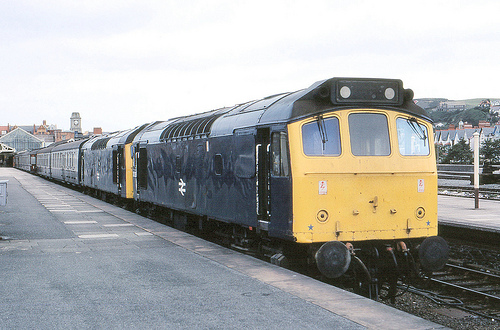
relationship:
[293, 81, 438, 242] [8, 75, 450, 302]
front of train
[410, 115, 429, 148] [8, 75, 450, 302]
windshield wiper of train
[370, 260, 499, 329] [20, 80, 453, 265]
train track next to train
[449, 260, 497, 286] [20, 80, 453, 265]
train track next to train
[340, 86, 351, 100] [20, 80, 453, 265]
headlight on front of train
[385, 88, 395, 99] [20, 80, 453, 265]
headlight on front of train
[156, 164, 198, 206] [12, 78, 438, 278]
logo on side of train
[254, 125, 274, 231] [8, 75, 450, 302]
area to get into train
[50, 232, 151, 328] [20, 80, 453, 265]
cement platform on left side of train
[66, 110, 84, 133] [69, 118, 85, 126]
tower with clock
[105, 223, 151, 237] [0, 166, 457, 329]
rectangle in cement platform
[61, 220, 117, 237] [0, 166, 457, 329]
rectangle in cement platform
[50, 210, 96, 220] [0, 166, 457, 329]
rectangle in cement platform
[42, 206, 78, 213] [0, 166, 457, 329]
rectangle in cement platform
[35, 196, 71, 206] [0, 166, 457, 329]
rectangle in cement platform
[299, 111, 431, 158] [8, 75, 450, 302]
windows of a train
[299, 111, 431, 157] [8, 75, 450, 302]
windshield of train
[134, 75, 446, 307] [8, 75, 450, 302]
train car attached to train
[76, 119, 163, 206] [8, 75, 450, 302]
train car attached to train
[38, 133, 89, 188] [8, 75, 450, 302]
train car attached to train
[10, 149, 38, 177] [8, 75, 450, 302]
train car attached to train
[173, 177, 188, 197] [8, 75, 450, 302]
logo on side of train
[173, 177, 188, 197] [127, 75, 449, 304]
logo on side of train car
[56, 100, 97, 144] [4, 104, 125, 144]
tower build in back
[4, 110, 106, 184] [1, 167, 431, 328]
building in train station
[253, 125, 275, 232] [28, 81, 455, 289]
open door in train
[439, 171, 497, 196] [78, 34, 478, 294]
train track behind train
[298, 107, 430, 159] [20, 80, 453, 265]
windows in train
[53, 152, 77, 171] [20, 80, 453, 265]
windows in train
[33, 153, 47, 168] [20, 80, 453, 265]
windows in train